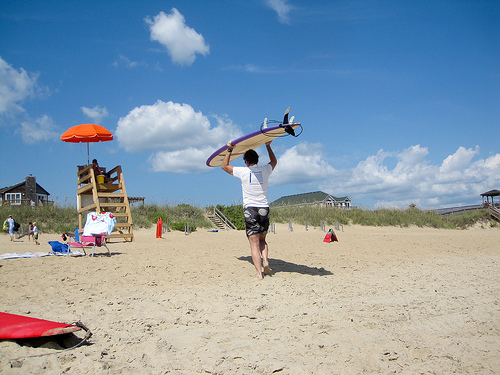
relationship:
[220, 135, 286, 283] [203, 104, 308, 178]
man carrying surfboard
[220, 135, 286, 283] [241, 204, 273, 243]
man wearing shorts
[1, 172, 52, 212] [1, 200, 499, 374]
house near beach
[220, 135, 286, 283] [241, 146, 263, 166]
man has hair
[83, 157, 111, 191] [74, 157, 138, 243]
lifeguard in chair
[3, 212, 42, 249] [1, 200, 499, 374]
family on top of beach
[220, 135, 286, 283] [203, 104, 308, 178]
man holding surfboard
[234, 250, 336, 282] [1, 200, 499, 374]
shadow on top of beach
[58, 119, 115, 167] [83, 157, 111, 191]
umbrella above lifeguard